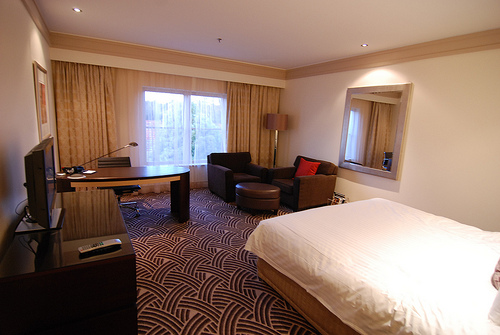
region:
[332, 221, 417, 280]
the white sheets on the bed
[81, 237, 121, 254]
a controller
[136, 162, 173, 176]
a desk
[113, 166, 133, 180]
the desk is brown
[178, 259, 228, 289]
a design on the carpet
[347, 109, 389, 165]
a mirror on the wall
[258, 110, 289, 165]
a lamp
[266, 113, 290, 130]
a lamp shade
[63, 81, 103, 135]
the curtains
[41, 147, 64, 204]
a television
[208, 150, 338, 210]
two brown armchairs in the corner of a room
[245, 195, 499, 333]
a bed with white bedding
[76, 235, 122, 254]
a silver remote on a desk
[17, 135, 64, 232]
a TV on a silver stand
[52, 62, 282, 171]
light brown curtains on the window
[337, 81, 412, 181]
a silver framed mirror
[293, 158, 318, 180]
a red cushion on an armchair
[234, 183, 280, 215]
a brown poof in front of two armchairs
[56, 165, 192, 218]
an oval table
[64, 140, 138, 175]
a silver lamp on a table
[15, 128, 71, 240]
A side view of a flat screen TV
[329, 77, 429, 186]
A mirror on the wall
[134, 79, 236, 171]
A window in the background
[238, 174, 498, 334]
A bed in the foreground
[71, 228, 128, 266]
A TV remote in the foreground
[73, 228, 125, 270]
TV remote is silver in color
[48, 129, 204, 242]
A wooden table in the background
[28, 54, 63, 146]
A side view of a picture frame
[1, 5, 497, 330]
Photo was taken indoors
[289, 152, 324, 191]
A red pillow in the background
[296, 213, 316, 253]
par tof a line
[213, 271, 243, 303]
part of a floor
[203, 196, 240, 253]
part of a floor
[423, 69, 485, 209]
this is the wall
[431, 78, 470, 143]
the wall is white in color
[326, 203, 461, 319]
this is a bed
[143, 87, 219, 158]
this is the window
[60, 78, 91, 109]
the curtain is brown in color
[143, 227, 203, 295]
this is the floor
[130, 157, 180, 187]
this is a table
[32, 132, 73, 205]
this is a television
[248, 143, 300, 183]
this is a chair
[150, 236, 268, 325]
black and tan floor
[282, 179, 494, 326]
white sheet on bed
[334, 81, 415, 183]
large mirror affixed to wall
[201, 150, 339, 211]
large cushion chairs beside window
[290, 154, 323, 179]
red decorative pillow on chair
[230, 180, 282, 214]
round brown ottoman in front of chairs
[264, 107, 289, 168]
tall pole lamp for lighting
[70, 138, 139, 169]
extended arm light on desk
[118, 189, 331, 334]
colorful carpet with contemporary design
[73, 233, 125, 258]
television remote on desk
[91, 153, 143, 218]
chair sitting with desk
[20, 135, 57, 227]
tv on top of the dresser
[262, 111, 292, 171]
lamp in the corner